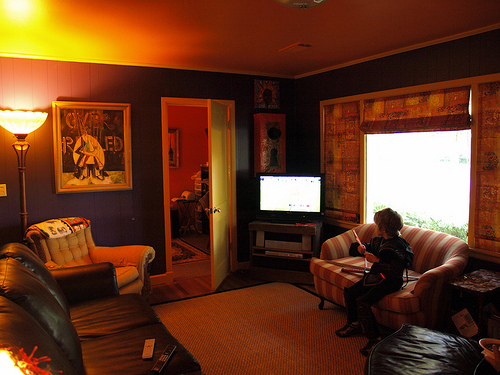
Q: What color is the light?
A: Orange.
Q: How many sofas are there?
A: Two.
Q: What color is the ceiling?
A: Cream.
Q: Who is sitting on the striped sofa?
A: The boy.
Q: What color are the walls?
A: Blue.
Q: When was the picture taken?
A: Daytime.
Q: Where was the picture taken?
A: In a house.